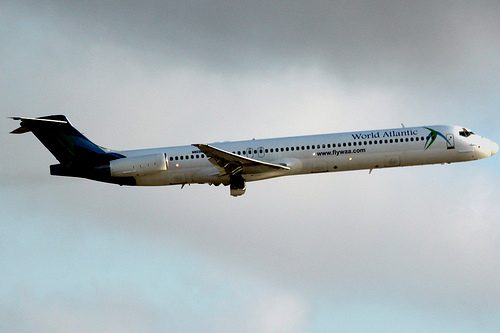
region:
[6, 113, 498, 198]
black and white airplane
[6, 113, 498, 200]
passenger airplane is flying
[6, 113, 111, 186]
dark tail fin of an airplane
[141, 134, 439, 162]
several windows in a row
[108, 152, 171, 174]
large engine on the back of an airplane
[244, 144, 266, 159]
airplane emergency exit doors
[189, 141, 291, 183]
wing of an airplane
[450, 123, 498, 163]
sun shining on the nose of an airplane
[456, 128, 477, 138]
cockpit windows on an airplane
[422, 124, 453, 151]
design on the side of an airplane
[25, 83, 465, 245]
the plane is flying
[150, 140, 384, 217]
the plane has multiple windows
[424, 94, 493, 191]
the plane has a green logo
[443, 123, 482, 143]
windows are on the front of the plane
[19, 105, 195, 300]
the plane has a blue tail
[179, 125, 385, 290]
the plane has a wing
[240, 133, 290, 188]
two emergency doors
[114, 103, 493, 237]
the plane is in a ir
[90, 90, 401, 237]
the plane si in motion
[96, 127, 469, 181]
the plane is moving horizontly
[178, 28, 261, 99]
the sky is coverd of clouds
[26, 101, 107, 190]
the tail is black in color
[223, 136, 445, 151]
the windows are aranged on same lane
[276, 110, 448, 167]
the plane is gray in color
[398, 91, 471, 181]
the plane has a logo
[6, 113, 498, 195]
airplane is flying in the sky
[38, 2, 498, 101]
dark cloud above airplane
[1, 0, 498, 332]
sky behind airplane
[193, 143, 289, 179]
metal wing attached to airplane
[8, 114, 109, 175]
tail is painted blue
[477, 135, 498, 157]
airplane nose is white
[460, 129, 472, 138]
windshield above nose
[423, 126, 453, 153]
logo painted on airplane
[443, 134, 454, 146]
airplane door is closed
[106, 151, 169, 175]
large engine behind airplane wing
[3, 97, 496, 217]
A commercial airplane in the air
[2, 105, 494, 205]
A commercial airplane in the air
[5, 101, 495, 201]
A commercial airplane in the air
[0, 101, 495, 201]
A commercial airplane in the air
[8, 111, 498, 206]
A commercial airplane in the air